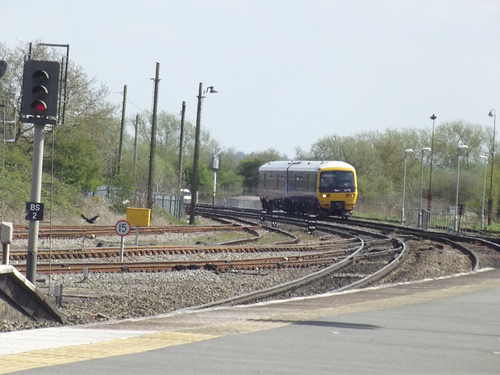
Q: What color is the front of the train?
A: Yellow.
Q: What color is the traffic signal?
A: Red.